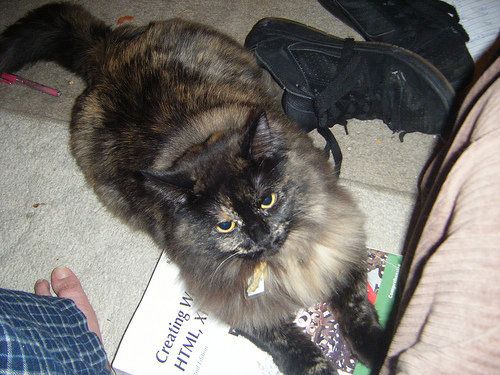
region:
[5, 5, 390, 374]
brown tan and black cat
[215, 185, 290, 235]
yellow and blue eyes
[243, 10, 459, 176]
show is black and worn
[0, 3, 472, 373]
multi-color cat is laying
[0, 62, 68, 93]
pink plastic pen next to cat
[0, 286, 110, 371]
blue and white plaid pants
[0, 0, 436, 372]
white and dirty carpet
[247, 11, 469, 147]
black shoe with brown sole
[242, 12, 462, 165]
black shoe with tied laces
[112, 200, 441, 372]
white and green book under cat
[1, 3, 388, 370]
Large fluffy cat on the ground.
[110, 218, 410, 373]
Text book cat is laying on.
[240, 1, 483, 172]
Black tennis shoes next to cat.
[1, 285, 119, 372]
Plaid pants on the person.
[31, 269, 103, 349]
Two toes showing on person's foot.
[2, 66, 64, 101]
Pink pen laying on ground.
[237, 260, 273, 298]
Tag on the cat.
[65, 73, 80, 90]
Crumb on the carpet.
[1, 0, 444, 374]
Carpet on the floor.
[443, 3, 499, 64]
Paper with writing in the background.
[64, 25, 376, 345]
reclined cat looking up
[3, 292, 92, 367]
plaid blue and white pant leg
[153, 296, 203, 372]
words on book cover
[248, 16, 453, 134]
black sneaker on side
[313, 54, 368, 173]
black laces on she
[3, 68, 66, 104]
pink pen on floor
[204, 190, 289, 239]
cat eyes with dilated pupils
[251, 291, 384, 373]
two paws on book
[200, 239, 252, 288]
whisker on cat's face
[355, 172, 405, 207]
edge of gray rug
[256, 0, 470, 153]
black tennis shoes laying on floor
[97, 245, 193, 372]
magazine laying on floor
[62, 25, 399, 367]
black and orange cat sitting on floor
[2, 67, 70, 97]
pink ink pen on floor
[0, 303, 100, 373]
plaid pants leg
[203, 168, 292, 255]
orange and black cat eyes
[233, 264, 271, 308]
tag on cat collar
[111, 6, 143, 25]
orange trash laying on floor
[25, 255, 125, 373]
left bare foot of person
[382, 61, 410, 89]
white design on side of tennis shoe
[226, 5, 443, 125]
a black tennis shoe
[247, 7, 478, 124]
a pair of black tennis shoes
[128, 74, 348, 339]
a multicolored cat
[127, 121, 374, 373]
a cat sitting on a book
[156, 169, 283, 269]
a cat with blue and yellow eyes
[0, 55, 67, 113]
a pink ink pen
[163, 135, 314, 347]
a cat wearing a collar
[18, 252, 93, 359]
someone's bare foot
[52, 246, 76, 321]
a persons big toe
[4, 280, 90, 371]
a person wearing blue plaid pants